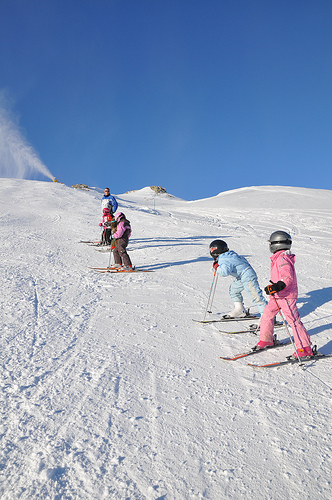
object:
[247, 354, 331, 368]
ski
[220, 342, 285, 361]
ski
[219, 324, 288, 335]
ski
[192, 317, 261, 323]
ski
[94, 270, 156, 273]
ski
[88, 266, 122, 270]
ski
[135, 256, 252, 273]
shadow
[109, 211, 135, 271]
child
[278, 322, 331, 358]
shadow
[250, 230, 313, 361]
child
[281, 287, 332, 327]
shadow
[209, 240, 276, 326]
child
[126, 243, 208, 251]
shadow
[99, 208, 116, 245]
child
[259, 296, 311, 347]
snow pants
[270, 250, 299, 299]
jacket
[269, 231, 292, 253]
helmet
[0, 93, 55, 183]
snow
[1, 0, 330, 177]
sky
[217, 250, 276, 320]
snowsuit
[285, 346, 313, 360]
boot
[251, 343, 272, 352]
boot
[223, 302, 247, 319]
boot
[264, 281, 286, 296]
glove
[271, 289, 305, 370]
ski pole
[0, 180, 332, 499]
snow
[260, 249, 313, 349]
snowsuit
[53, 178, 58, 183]
machine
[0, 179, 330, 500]
mountain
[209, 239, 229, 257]
helmet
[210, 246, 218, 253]
logo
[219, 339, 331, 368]
skis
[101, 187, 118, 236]
skier